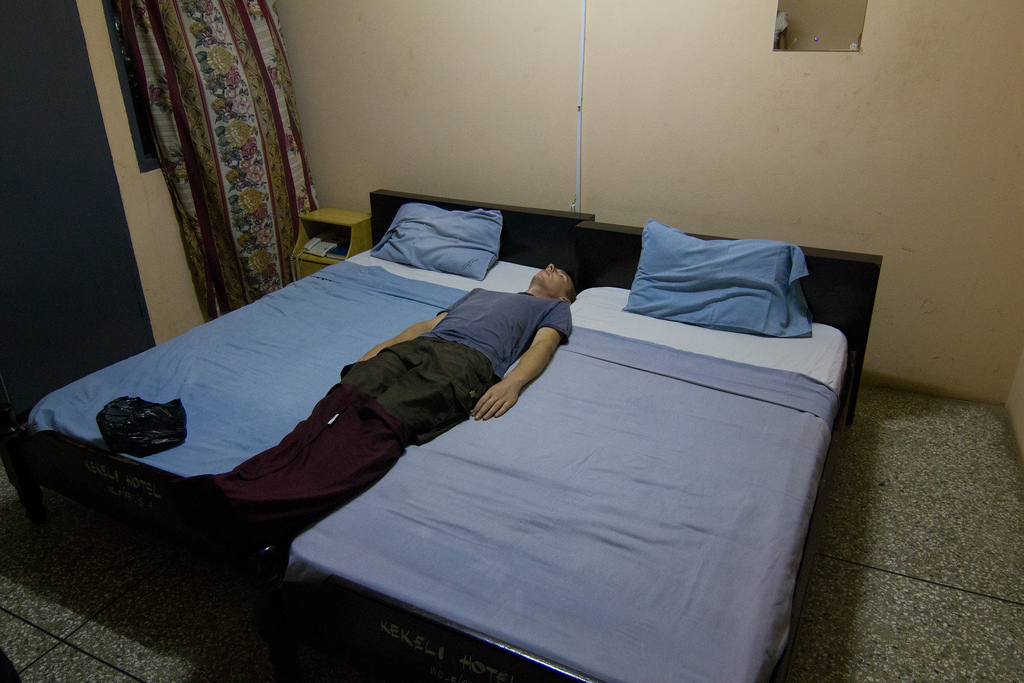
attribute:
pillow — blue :
[375, 197, 500, 286]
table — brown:
[288, 206, 366, 280]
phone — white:
[301, 234, 333, 257]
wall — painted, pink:
[66, 0, 1021, 418]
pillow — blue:
[627, 221, 815, 343]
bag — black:
[98, 398, 191, 459]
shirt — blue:
[420, 285, 570, 372]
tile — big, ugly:
[41, 539, 307, 679]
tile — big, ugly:
[0, 474, 182, 631]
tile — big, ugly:
[29, 642, 138, 680]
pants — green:
[330, 333, 490, 439]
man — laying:
[205, 261, 594, 594]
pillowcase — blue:
[616, 210, 814, 334]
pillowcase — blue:
[374, 199, 511, 279]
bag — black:
[93, 393, 188, 464]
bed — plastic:
[23, 187, 596, 592]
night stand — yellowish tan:
[282, 206, 368, 276]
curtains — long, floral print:
[101, 0, 330, 318]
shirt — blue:
[420, 288, 573, 386]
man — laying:
[129, 253, 581, 568]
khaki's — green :
[342, 338, 502, 447]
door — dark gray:
[1, 1, 157, 359]